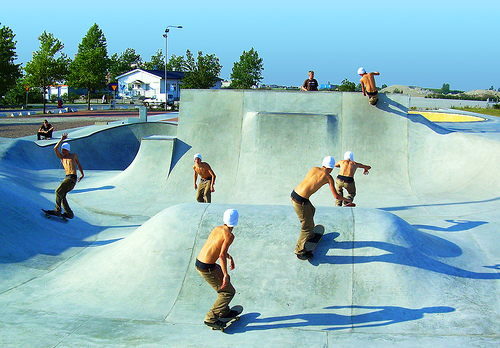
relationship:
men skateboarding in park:
[47, 146, 383, 267] [8, 11, 493, 338]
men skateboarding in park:
[40, 136, 405, 296] [8, 11, 493, 338]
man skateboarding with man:
[285, 155, 336, 273] [326, 145, 373, 203]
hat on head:
[222, 209, 240, 233] [208, 203, 246, 227]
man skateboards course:
[185, 199, 272, 332] [35, 98, 462, 346]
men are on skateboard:
[22, 119, 378, 302] [199, 299, 248, 339]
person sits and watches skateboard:
[27, 111, 64, 141] [280, 219, 335, 265]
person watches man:
[35, 118, 55, 140] [288, 154, 337, 261]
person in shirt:
[35, 118, 55, 140] [36, 120, 56, 133]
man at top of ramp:
[304, 69, 318, 90] [179, 87, 416, 175]